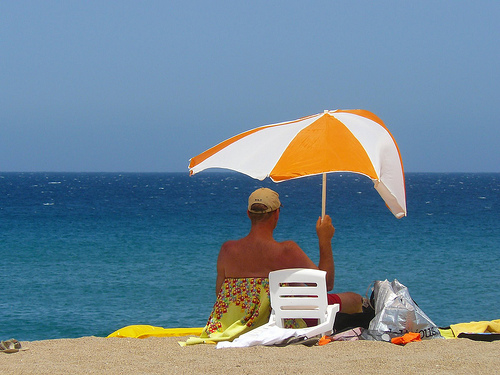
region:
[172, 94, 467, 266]
a beach umbrella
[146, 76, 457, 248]
a white and orange beach umbrella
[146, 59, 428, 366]
a man holding a umbrella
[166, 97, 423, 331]
a man holding a orange and white umbrella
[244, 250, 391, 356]
a white beach chair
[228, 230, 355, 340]
a white chair on the beach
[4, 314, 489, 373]
tan sand on the beach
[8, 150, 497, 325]
blue ocean water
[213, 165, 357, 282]
a man wearing a hat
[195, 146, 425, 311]
a man wearing no shirt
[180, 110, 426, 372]
a tanned man holding on to umbrella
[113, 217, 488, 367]
a man at the beach by himself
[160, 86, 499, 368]
a man with an orange and white umbrella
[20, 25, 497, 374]
a man trying to not get any tanner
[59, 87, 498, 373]
a man with no shirt on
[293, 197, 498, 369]
a man with a bag next to him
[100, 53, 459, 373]
a man in a yellow hat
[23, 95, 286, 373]
a blue ocean at the beach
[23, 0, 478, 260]
clear sky with no clouds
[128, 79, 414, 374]
a caucasian man by himself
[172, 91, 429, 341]
Man holding an umbrella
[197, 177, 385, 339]
Man is in the beach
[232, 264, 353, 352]
White chair next to man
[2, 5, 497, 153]
Sky is blue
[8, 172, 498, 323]
Water is blue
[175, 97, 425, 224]
Umbrella is white and orange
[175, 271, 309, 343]
Beach towel is green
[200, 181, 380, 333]
Man wears red short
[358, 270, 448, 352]
Bag next to man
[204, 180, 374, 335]
Man wears a hat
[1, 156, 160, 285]
beautiful blue ocean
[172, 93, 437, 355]
a man sits under an umbrella on the beach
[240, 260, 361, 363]
a small white beach chair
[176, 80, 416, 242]
a yellow and white beach umbrella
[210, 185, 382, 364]
a man with a hat sitting on the beach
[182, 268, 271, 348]
a flowered beach towel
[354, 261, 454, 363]
a bag sits in the sand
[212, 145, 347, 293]
a man hold onto the umbrella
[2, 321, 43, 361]
a shoe in the sand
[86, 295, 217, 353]
a yellow inflatable beach toy in the sand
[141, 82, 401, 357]
man is holding an umbrella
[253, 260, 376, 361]
the seat is white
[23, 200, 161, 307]
the water is calm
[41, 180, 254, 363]
the water is blue green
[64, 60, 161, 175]
the sky is blue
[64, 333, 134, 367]
the sand is brown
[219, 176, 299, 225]
man is wearing a cap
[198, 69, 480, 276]
the umbrella is orange and white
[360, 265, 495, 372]
the bag is silver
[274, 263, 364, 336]
the shorts are red